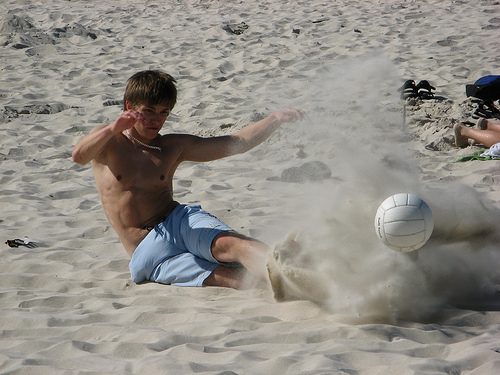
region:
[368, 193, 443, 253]
a white volley ball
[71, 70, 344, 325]
a boy in the sand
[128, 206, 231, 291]
blue shorts on a boy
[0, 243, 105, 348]
tracks in the sand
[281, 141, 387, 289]
dusty sand in the air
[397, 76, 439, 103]
a black sandals in the sand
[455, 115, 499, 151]
a person legs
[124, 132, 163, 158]
a white necklace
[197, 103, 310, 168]
a arm in the air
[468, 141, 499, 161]
a blanket on the beach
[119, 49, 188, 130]
boy has brown hair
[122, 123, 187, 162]
boy wears shell necklace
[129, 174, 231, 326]
boy has brown shorts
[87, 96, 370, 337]
boy dives into sand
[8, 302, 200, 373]
sand is light brown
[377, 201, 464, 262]
volleyball in front of cloud of sand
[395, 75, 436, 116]
black shoes on sand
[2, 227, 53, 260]
glasses next to boy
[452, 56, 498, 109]
blue object on sand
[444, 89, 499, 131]
person lying on sand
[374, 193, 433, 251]
white volley ball flying through air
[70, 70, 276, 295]
young man kicking volley ball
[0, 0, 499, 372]
tan sandy beach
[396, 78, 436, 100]
pair of black sandals on sand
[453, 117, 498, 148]
person's bare legs and sandy feet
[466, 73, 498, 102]
blue and black bag on sand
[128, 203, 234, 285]
light blue shorts on young man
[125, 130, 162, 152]
white necklace on young man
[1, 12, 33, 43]
small pile of sand on sandy beach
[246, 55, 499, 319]
sand and volley ball kicked through air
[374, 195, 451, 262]
a ball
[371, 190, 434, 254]
the ball is white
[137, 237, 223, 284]
the man is wearing blue shorts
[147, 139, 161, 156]
a white necklace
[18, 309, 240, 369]
the sand on the beach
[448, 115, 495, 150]
a persons leg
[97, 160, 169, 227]
the mans chest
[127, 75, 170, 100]
brown hair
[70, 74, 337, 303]
man is sitting on the sand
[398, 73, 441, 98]
shoes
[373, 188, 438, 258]
white volleyball is airbound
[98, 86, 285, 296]
man sitting on the beach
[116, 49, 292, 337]
a man wearing blue shorts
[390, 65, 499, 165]
a person laying on the sand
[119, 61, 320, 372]
a person with brown hair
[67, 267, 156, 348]
sand on the beach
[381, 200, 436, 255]
hard white volleyball in air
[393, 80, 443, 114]
a pair of black shoes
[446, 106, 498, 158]
a person's bare feet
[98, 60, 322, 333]
a man sitting on the beach